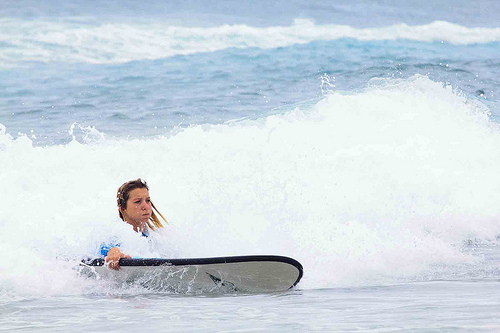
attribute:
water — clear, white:
[301, 147, 401, 219]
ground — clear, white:
[383, 152, 410, 174]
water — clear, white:
[0, 1, 498, 329]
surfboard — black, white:
[84, 245, 310, 299]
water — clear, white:
[13, 41, 491, 235]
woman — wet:
[96, 177, 182, 270]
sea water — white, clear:
[156, 297, 463, 331]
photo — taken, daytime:
[2, 3, 497, 331]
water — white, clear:
[277, 293, 442, 325]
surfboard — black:
[118, 251, 305, 291]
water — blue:
[292, 25, 439, 120]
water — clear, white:
[331, 284, 499, 325]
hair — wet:
[116, 181, 153, 217]